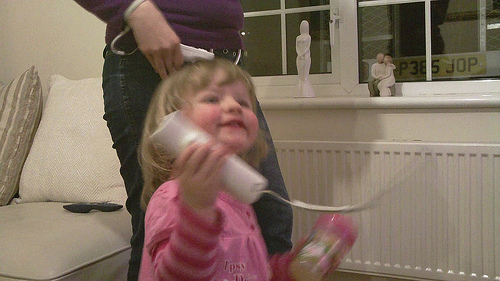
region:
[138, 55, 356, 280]
Girl holding a Wii controller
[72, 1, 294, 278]
Woman holding a Wii controller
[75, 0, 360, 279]
Woman and girl playing video games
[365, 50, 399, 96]
Statue of a man and woman holding each other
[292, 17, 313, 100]
White sculpture of a naked woman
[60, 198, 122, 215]
Black remote control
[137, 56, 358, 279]
Girl holding a sippy cup of juice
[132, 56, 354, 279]
Blonde haired girl wearing a pink shirt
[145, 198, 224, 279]
Light pink and dark pink stripes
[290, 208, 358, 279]
Sippy cup with a pink lid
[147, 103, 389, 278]
the girl is holding a wii remote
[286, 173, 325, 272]
the girl is holding a cup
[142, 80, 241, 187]
the girl has long hair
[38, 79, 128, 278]
the couch is white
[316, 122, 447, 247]
the wall is striped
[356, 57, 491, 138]
numbers are in the window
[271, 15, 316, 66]
a statue is by the window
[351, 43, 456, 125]
a figurine is by the window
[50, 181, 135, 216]
a remote is on the couch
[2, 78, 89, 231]
the pillow is striped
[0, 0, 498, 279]
picture taken inside family home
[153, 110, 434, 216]
little girl is holding a wii remote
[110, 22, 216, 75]
father is holding a wii remote also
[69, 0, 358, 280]
two people interacting and playing a video game together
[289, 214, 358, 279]
holding juice cup in hand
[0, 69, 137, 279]
couch is positioned behind people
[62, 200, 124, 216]
black remote sits on edge of sofa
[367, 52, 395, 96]
wooden sculpture setting on window seal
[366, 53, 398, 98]
man and woman in loving embrace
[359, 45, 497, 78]
sign remains outside window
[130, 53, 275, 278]
small girl with wii remote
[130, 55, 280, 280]
young blond girl with pink shirt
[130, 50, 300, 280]
smiling toddler girl with wii remote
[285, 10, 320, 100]
white statue of woman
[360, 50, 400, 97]
statuette of man and woman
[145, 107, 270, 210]
nintendo wii remote control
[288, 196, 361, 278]
sippy cup for child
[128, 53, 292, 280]
toddler playing wii video game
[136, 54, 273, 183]
smiling child with pink cheeks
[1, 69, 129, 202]
two throw pillows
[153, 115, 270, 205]
a white game controller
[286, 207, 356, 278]
a pink sippie cup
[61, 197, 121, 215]
a black remote control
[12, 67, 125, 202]
part of a beige couch pillow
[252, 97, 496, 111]
part of a window sill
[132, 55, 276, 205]
a girl's blonde hair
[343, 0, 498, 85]
part of a window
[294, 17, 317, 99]
a tall white statue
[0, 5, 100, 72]
part of a white wall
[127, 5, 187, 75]
the hand of a man